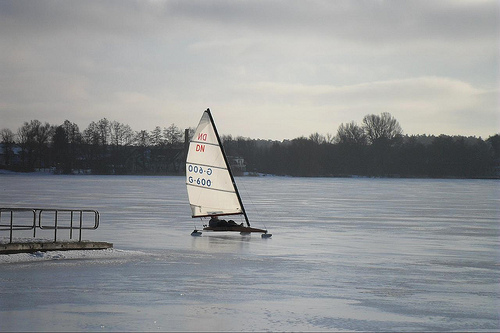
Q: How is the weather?
A: It is cloudy.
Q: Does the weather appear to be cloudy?
A: Yes, it is cloudy.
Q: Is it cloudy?
A: Yes, it is cloudy.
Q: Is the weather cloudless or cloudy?
A: It is cloudy.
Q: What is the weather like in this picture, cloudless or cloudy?
A: It is cloudy.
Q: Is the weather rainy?
A: No, it is cloudy.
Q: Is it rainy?
A: No, it is cloudy.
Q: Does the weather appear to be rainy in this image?
A: No, it is cloudy.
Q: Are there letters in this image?
A: Yes, there are letters.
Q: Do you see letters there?
A: Yes, there are letters.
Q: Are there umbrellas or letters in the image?
A: Yes, there are letters.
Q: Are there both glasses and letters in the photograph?
A: No, there are letters but no glasses.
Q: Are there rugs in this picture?
A: No, there are no rugs.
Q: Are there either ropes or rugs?
A: No, there are no rugs or ropes.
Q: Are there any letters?
A: Yes, there are letters.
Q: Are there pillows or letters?
A: Yes, there are letters.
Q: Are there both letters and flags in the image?
A: No, there are letters but no flags.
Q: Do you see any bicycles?
A: No, there are no bicycles.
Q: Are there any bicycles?
A: No, there are no bicycles.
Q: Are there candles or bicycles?
A: No, there are no bicycles or candles.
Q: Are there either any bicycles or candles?
A: No, there are no bicycles or candles.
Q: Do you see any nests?
A: No, there are no nests.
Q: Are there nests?
A: No, there are no nests.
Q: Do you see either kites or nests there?
A: No, there are no nests or kites.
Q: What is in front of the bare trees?
A: The water is in front of the trees.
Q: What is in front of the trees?
A: The water is in front of the trees.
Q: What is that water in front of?
A: The water is in front of the trees.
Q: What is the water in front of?
A: The water is in front of the trees.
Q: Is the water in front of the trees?
A: Yes, the water is in front of the trees.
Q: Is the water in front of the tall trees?
A: Yes, the water is in front of the trees.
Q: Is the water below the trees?
A: Yes, the water is below the trees.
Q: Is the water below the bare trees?
A: Yes, the water is below the trees.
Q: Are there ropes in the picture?
A: No, there are no ropes.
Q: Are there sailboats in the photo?
A: Yes, there is a sailboat.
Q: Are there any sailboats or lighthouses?
A: Yes, there is a sailboat.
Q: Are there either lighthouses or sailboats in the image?
A: Yes, there is a sailboat.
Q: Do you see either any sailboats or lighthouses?
A: Yes, there is a sailboat.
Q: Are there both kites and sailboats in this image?
A: No, there is a sailboat but no kites.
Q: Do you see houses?
A: No, there are no houses.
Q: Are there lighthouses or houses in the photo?
A: No, there are no houses or lighthouses.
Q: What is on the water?
A: The sailboat is on the water.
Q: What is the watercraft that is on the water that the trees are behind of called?
A: The watercraft is a sailboat.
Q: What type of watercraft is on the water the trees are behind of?
A: The watercraft is a sailboat.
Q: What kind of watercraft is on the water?
A: The watercraft is a sailboat.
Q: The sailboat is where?
A: The sailboat is on the water.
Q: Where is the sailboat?
A: The sailboat is on the water.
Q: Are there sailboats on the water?
A: Yes, there is a sailboat on the water.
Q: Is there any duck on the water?
A: No, there is a sailboat on the water.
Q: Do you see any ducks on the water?
A: No, there is a sailboat on the water.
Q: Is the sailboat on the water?
A: Yes, the sailboat is on the water.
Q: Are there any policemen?
A: No, there are no policemen.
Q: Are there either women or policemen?
A: No, there are no policemen or women.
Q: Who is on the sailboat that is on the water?
A: The man is on the sailboat.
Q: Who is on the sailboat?
A: The man is on the sailboat.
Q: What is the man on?
A: The man is on the sailboat.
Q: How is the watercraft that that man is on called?
A: The watercraft is a sailboat.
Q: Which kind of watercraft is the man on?
A: The man is on the sailboat.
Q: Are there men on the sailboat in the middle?
A: Yes, there is a man on the sailboat.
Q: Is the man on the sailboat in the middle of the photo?
A: Yes, the man is on the sailboat.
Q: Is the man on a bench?
A: No, the man is on the sailboat.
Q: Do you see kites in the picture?
A: No, there are no kites.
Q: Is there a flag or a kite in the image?
A: No, there are no kites or flags.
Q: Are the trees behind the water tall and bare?
A: Yes, the trees are tall and bare.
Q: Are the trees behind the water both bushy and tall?
A: No, the trees are tall but bare.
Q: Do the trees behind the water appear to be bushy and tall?
A: No, the trees are tall but bare.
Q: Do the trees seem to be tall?
A: Yes, the trees are tall.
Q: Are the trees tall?
A: Yes, the trees are tall.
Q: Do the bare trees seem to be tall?
A: Yes, the trees are tall.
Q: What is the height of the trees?
A: The trees are tall.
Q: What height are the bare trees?
A: The trees are tall.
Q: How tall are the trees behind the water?
A: The trees are tall.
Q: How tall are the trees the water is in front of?
A: The trees are tall.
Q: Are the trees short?
A: No, the trees are tall.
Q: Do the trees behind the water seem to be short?
A: No, the trees are tall.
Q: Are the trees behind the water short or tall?
A: The trees are tall.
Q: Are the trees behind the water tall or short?
A: The trees are tall.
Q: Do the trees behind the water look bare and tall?
A: Yes, the trees are bare and tall.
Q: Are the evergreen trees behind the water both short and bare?
A: No, the trees are bare but tall.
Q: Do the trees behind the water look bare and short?
A: No, the trees are bare but tall.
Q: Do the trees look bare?
A: Yes, the trees are bare.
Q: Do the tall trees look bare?
A: Yes, the trees are bare.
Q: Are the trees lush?
A: No, the trees are bare.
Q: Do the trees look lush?
A: No, the trees are bare.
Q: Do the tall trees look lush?
A: No, the trees are bare.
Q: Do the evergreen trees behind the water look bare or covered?
A: The trees are bare.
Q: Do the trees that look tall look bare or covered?
A: The trees are bare.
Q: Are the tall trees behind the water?
A: Yes, the trees are behind the water.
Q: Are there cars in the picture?
A: No, there are no cars.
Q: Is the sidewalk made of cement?
A: Yes, the sidewalk is made of cement.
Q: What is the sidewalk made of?
A: The sidewalk is made of concrete.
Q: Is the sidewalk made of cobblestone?
A: No, the sidewalk is made of cement.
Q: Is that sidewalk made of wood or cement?
A: The sidewalk is made of cement.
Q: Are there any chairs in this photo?
A: No, there are no chairs.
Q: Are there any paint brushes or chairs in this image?
A: No, there are no chairs or paint brushes.